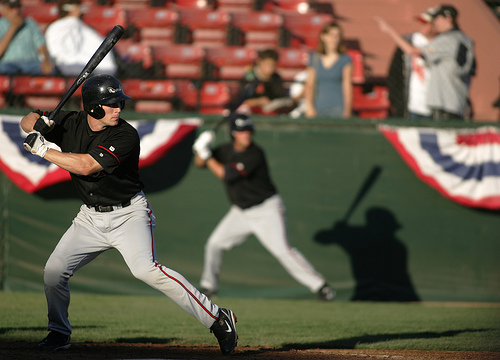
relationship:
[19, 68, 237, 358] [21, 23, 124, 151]
man are holding bat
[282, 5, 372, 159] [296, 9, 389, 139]
woman in dress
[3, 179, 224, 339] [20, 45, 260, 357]
pants on man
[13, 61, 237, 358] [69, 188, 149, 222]
man wearing belt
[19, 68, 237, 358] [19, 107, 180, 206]
man wearing shirt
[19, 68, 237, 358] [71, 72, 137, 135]
man wearing helmet